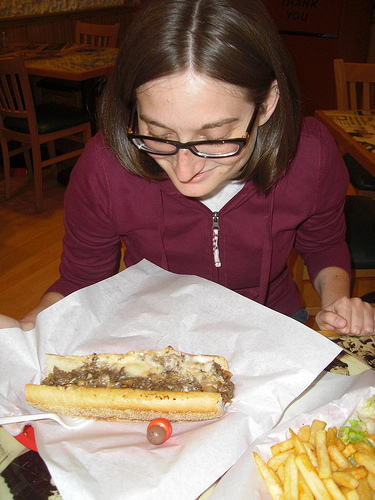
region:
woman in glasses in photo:
[81, 22, 305, 245]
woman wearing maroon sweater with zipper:
[55, 136, 345, 302]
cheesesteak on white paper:
[23, 288, 259, 468]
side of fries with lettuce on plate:
[236, 392, 374, 498]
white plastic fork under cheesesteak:
[2, 397, 104, 441]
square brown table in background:
[315, 91, 374, 186]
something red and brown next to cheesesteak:
[102, 402, 187, 459]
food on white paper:
[26, 267, 361, 460]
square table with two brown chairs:
[8, 28, 129, 167]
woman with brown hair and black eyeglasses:
[97, 34, 295, 223]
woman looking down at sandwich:
[22, 7, 318, 483]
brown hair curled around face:
[91, 5, 302, 200]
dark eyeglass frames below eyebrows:
[120, 95, 262, 167]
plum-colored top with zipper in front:
[40, 115, 357, 295]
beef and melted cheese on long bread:
[16, 324, 235, 415]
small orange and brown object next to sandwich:
[141, 414, 177, 453]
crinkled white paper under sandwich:
[2, 255, 333, 495]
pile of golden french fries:
[242, 411, 370, 494]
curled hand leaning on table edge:
[304, 270, 370, 336]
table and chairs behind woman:
[1, 51, 365, 195]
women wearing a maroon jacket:
[65, 16, 341, 279]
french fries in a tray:
[265, 422, 372, 490]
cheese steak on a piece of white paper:
[47, 331, 238, 415]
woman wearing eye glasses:
[130, 18, 300, 192]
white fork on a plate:
[16, 398, 89, 422]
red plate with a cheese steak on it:
[13, 427, 48, 453]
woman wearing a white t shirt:
[87, 7, 283, 260]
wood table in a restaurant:
[26, 19, 113, 81]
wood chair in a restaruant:
[327, 50, 374, 114]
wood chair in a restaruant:
[11, 59, 91, 165]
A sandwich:
[28, 325, 268, 435]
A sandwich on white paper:
[21, 351, 253, 436]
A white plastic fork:
[10, 398, 101, 447]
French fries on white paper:
[272, 411, 368, 493]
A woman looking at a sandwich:
[52, 93, 333, 412]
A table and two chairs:
[11, 23, 113, 212]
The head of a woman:
[76, 53, 296, 260]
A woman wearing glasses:
[113, 116, 312, 263]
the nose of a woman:
[150, 146, 225, 200]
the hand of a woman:
[309, 262, 366, 361]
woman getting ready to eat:
[18, 7, 367, 498]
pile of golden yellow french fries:
[263, 427, 366, 492]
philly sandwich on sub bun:
[44, 353, 232, 419]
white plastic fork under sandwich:
[1, 413, 94, 428]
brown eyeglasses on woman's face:
[123, 125, 258, 158]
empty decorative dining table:
[2, 24, 113, 204]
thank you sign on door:
[276, 0, 315, 22]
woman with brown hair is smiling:
[105, 6, 301, 199]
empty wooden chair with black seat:
[1, 56, 92, 213]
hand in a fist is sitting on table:
[315, 295, 373, 336]